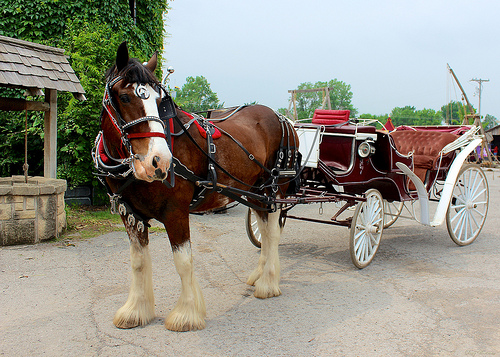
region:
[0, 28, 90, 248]
A well on the sidewalk.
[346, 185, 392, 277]
A white wagon wheel with many spokes.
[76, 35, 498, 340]
A horse pulling a stage coach.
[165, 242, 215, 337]
The horse's leg and hoof are white.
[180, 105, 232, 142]
The horse has a red saddle.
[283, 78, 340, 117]
A wooden frame is next to the coach.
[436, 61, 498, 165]
A large wooden apparatus in the background.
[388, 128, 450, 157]
The red velvet seat cushion of the coach.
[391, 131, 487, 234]
The coach has a white footpiece.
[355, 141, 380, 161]
A small metal horn at the front of the coach.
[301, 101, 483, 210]
red seats in a carriage.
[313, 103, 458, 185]
red interior in a carriage.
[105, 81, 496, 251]
a carriage attached to a horse.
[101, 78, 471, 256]
a horse attached to a carriage.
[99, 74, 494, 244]
a horse pulling a carriage.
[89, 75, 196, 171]
a cladsdale wearing black blinders.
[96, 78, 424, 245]
a cladsdale strapped to a carriage.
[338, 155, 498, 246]
white wheels installed on a carriage.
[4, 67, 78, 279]
a wishing well next to a horse.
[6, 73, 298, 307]
a horse next to a wishing well.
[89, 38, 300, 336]
Brown and white horse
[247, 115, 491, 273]
Horse-drawn carriage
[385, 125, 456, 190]
Red velvet seats in a carriage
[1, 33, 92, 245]
Stone water well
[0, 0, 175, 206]
Brick wall covered in leafy vines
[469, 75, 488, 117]
Telephone pole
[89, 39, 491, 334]
Horse rigged up to a carriage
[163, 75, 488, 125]
The tops of tall trees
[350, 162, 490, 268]
White wheels on a carriage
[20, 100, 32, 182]
Rope hanging down into a well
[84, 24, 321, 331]
this is a horse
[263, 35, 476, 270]
this is a cart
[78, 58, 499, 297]
this is a horse drawn cart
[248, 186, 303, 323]
the foot of a horse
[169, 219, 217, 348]
the foot of a horse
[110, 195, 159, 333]
the foot of a horse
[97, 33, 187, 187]
the head of a horse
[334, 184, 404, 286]
a wheel on a cart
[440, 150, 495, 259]
a wheel on a cart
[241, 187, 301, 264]
a wheel on a cart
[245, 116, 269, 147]
the horse is brown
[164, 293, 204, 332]
the feet are white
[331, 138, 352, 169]
the carriage is red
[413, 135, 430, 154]
the seat is light brown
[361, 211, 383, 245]
the wheel is white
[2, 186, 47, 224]
the well is weathered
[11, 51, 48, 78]
the roof has wood shingles on it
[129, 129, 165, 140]
the nose piece is red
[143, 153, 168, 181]
the horse has a pink nose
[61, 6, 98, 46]
the trees have green leaves